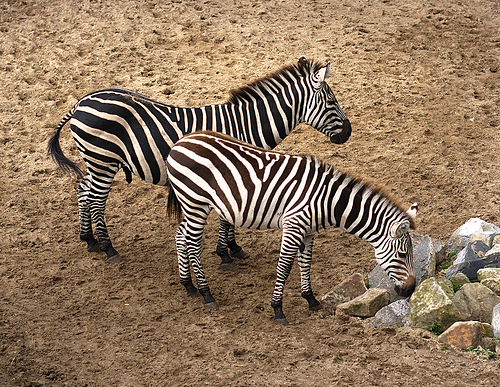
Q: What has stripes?
A: Zebra.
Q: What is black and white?
A: The zebra.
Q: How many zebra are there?
A: Two.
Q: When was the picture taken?
A: During the day.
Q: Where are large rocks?
A: On the ground.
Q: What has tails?
A: Two zebra.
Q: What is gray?
A: Rocks.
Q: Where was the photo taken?
A: In a zoo.